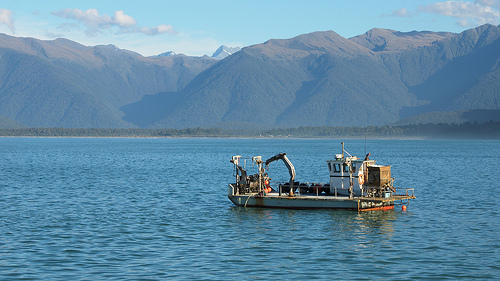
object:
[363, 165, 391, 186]
brown box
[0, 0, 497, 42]
sky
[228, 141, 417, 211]
boat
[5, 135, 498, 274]
water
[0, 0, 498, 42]
cloud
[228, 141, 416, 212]
airplane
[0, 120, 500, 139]
trees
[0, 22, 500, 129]
mountain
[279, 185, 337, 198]
railing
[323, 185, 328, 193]
objects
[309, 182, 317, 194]
objects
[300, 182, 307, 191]
objects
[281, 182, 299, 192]
objects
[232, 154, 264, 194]
poles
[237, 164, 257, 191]
panels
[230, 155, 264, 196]
rod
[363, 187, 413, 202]
platform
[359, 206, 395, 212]
stripe